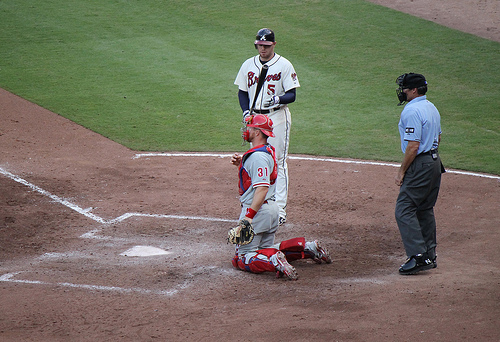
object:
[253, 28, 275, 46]
hat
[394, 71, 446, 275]
umpire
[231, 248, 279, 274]
shin guard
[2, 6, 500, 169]
grass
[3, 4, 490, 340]
field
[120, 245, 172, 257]
plate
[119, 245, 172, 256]
diamond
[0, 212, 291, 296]
baseball base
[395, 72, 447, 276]
man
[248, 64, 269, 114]
baseball bat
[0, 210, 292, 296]
batter's box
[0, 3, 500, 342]
baseball field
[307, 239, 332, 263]
cleat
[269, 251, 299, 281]
cleat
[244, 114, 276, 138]
helmet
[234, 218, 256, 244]
hand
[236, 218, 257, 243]
glove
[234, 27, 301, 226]
batter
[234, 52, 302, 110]
shirt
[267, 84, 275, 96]
number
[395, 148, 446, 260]
grey pants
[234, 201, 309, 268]
grey pants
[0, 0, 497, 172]
grassy turf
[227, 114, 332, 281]
man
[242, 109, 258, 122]
hand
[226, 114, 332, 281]
player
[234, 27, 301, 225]
player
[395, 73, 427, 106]
face mask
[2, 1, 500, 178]
turf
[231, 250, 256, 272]
knee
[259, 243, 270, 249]
knee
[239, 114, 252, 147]
face mask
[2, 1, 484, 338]
baseball game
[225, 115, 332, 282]
catcher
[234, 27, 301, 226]
man